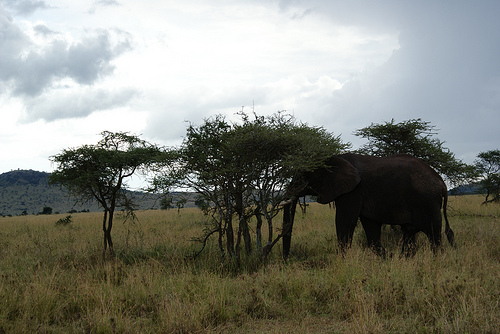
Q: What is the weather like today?
A: It is cloudy.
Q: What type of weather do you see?
A: It is cloudy.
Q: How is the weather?
A: It is cloudy.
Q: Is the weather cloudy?
A: Yes, it is cloudy.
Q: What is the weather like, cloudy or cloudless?
A: It is cloudy.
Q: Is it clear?
A: No, it is cloudy.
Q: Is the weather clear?
A: No, it is cloudy.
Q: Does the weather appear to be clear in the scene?
A: No, it is cloudy.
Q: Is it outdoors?
A: Yes, it is outdoors.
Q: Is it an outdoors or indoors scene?
A: It is outdoors.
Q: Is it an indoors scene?
A: No, it is outdoors.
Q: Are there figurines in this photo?
A: No, there are no figurines.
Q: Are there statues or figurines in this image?
A: No, there are no figurines or statues.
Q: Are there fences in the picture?
A: No, there are no fences.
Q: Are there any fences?
A: No, there are no fences.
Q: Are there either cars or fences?
A: No, there are no fences or cars.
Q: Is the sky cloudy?
A: Yes, the sky is cloudy.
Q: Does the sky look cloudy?
A: Yes, the sky is cloudy.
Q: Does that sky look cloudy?
A: Yes, the sky is cloudy.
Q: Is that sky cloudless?
A: No, the sky is cloudy.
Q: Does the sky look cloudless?
A: No, the sky is cloudy.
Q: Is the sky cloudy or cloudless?
A: The sky is cloudy.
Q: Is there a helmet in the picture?
A: No, there are no helmets.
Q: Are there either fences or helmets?
A: No, there are no helmets or fences.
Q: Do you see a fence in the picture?
A: No, there are no fences.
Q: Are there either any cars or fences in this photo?
A: No, there are no fences or cars.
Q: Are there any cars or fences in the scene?
A: No, there are no fences or cars.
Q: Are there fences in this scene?
A: No, there are no fences.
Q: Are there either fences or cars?
A: No, there are no fences or cars.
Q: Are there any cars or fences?
A: No, there are no fences or cars.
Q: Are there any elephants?
A: Yes, there is an elephant.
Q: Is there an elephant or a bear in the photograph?
A: Yes, there is an elephant.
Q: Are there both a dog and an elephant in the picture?
A: No, there is an elephant but no dogs.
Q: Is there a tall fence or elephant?
A: Yes, there is a tall elephant.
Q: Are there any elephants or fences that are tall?
A: Yes, the elephant is tall.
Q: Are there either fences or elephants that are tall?
A: Yes, the elephant is tall.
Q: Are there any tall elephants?
A: Yes, there is a tall elephant.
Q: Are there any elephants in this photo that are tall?
A: Yes, there is an elephant that is tall.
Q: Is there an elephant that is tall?
A: Yes, there is an elephant that is tall.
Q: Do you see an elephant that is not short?
A: Yes, there is a tall elephant.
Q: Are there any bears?
A: No, there are no bears.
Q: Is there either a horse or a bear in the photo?
A: No, there are no bears or horses.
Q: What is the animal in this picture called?
A: The animal is an elephant.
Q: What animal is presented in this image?
A: The animal is an elephant.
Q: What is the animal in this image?
A: The animal is an elephant.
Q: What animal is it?
A: The animal is an elephant.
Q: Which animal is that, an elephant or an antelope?
A: This is an elephant.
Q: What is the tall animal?
A: The animal is an elephant.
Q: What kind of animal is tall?
A: The animal is an elephant.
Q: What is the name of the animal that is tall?
A: The animal is an elephant.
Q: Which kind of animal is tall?
A: The animal is an elephant.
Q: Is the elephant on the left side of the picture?
A: No, the elephant is on the right of the image.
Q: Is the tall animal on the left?
A: No, the elephant is on the right of the image.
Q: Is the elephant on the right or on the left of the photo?
A: The elephant is on the right of the image.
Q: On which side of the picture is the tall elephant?
A: The elephant is on the right of the image.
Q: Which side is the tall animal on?
A: The elephant is on the right of the image.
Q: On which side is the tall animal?
A: The elephant is on the right of the image.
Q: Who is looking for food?
A: The elephant is looking for food.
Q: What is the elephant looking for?
A: The elephant is looking for food.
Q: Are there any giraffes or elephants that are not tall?
A: No, there is an elephant but it is tall.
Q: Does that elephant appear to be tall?
A: Yes, the elephant is tall.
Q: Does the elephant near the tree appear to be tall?
A: Yes, the elephant is tall.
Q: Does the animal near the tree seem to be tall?
A: Yes, the elephant is tall.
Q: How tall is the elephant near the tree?
A: The elephant is tall.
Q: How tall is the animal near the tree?
A: The elephant is tall.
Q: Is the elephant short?
A: No, the elephant is tall.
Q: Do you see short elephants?
A: No, there is an elephant but it is tall.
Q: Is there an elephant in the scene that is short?
A: No, there is an elephant but it is tall.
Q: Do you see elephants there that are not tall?
A: No, there is an elephant but it is tall.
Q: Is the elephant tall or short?
A: The elephant is tall.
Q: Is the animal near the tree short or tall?
A: The elephant is tall.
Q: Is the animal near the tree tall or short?
A: The elephant is tall.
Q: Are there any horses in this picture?
A: No, there are no horses.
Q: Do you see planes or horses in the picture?
A: No, there are no horses or planes.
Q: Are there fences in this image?
A: No, there are no fences.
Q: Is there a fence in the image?
A: No, there are no fences.